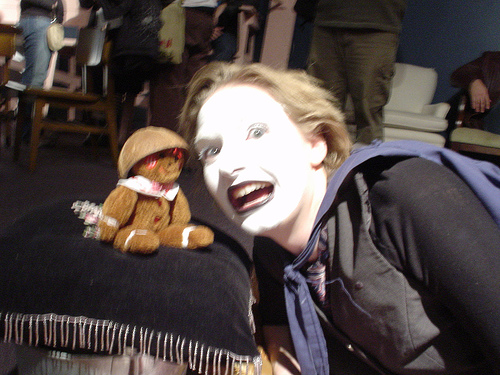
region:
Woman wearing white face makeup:
[192, 78, 325, 248]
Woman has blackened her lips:
[220, 176, 293, 220]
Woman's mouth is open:
[220, 173, 284, 216]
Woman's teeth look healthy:
[224, 180, 290, 211]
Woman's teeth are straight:
[220, 177, 281, 213]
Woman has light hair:
[166, 55, 354, 164]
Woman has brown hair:
[172, 60, 364, 176]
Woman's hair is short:
[168, 45, 354, 175]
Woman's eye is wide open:
[245, 118, 280, 148]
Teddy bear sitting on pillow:
[90, 120, 223, 273]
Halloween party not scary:
[1, 2, 495, 304]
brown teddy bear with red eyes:
[106, 112, 199, 275]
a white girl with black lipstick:
[220, 183, 276, 228]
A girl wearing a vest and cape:
[281, 160, 498, 357]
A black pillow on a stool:
[43, 202, 203, 374]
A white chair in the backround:
[410, 55, 448, 139]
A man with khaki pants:
[313, 36, 403, 103]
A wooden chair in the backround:
[26, 32, 126, 160]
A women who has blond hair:
[166, 53, 395, 149]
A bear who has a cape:
[101, 178, 203, 249]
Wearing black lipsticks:
[210, 172, 305, 239]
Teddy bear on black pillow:
[22, 144, 289, 368]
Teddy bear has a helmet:
[80, 98, 221, 263]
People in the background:
[12, 2, 437, 166]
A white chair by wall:
[302, 14, 473, 169]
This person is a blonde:
[185, 37, 369, 239]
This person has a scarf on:
[253, 125, 423, 347]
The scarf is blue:
[245, 85, 499, 270]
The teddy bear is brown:
[76, 115, 231, 273]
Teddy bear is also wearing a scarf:
[107, 157, 185, 212]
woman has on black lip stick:
[221, 179, 288, 214]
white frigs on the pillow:
[43, 309, 205, 358]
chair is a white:
[356, 64, 469, 156]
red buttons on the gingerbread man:
[154, 192, 164, 237]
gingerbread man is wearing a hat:
[103, 113, 193, 168]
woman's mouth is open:
[220, 178, 323, 224]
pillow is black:
[70, 260, 275, 320]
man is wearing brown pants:
[307, 15, 427, 138]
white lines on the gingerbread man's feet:
[79, 220, 218, 255]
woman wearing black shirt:
[393, 178, 483, 305]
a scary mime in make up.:
[175, 59, 352, 253]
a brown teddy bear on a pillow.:
[61, 111, 235, 275]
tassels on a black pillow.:
[0, 310, 261, 370]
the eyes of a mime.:
[184, 110, 290, 181]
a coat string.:
[287, 247, 324, 369]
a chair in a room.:
[366, 47, 473, 164]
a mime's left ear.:
[263, 102, 338, 190]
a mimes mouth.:
[211, 165, 285, 230]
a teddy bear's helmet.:
[101, 106, 206, 196]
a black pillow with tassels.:
[0, 186, 267, 373]